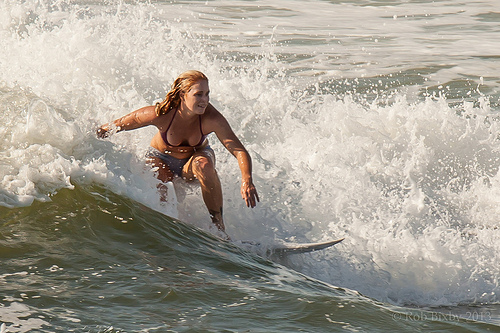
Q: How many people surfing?
A: One.